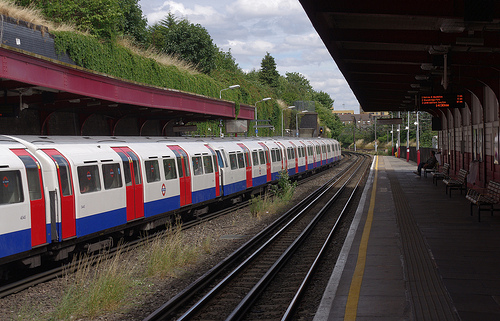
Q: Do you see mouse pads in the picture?
A: No, there are no mouse pads.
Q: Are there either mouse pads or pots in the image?
A: No, there are no mouse pads or pots.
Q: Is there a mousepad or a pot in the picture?
A: No, there are no mouse pads or pots.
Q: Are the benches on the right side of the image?
A: Yes, the benches are on the right of the image.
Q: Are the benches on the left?
A: No, the benches are on the right of the image.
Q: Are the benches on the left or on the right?
A: The benches are on the right of the image.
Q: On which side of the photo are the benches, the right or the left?
A: The benches are on the right of the image.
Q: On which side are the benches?
A: The benches are on the right of the image.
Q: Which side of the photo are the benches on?
A: The benches are on the right of the image.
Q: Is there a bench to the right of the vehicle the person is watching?
A: Yes, there are benches to the right of the train.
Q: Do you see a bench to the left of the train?
A: No, the benches are to the right of the train.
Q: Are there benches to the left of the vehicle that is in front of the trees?
A: No, the benches are to the right of the train.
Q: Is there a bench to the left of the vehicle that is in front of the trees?
A: No, the benches are to the right of the train.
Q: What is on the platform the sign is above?
A: The benches are on the platform.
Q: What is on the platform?
A: The benches are on the platform.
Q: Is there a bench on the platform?
A: Yes, there are benches on the platform.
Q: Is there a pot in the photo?
A: No, there are no pots.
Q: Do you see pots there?
A: No, there are no pots.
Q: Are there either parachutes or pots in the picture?
A: No, there are no pots or parachutes.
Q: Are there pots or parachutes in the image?
A: No, there are no pots or parachutes.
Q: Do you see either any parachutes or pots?
A: No, there are no pots or parachutes.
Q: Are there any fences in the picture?
A: No, there are no fences.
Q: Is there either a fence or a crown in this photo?
A: No, there are no fences or crowns.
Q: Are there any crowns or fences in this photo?
A: No, there are no fences or crowns.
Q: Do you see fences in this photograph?
A: No, there are no fences.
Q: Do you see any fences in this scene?
A: No, there are no fences.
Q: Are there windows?
A: Yes, there are windows.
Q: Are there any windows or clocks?
A: Yes, there are windows.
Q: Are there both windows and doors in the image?
A: Yes, there are both windows and doors.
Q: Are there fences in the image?
A: No, there are no fences.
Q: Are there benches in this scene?
A: Yes, there is a bench.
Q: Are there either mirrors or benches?
A: Yes, there is a bench.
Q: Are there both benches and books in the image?
A: No, there is a bench but no books.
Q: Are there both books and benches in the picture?
A: No, there is a bench but no books.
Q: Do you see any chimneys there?
A: No, there are no chimneys.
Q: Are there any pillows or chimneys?
A: No, there are no chimneys or pillows.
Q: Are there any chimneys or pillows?
A: No, there are no chimneys or pillows.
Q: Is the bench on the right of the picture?
A: Yes, the bench is on the right of the image.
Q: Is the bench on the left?
A: No, the bench is on the right of the image.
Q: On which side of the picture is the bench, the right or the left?
A: The bench is on the right of the image.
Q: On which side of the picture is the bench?
A: The bench is on the right of the image.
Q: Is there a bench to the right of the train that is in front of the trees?
A: Yes, there is a bench to the right of the train.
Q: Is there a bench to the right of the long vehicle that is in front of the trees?
A: Yes, there is a bench to the right of the train.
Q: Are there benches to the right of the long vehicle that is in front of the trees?
A: Yes, there is a bench to the right of the train.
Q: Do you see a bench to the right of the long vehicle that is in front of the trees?
A: Yes, there is a bench to the right of the train.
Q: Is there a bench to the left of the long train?
A: No, the bench is to the right of the train.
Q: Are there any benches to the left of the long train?
A: No, the bench is to the right of the train.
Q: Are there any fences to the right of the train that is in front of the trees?
A: No, there is a bench to the right of the train.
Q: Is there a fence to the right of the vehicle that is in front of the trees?
A: No, there is a bench to the right of the train.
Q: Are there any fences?
A: No, there are no fences.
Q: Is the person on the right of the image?
A: Yes, the person is on the right of the image.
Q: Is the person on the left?
A: No, the person is on the right of the image.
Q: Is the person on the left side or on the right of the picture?
A: The person is on the right of the image.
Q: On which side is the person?
A: The person is on the right of the image.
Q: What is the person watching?
A: The person is watching the train.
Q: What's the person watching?
A: The person is watching the train.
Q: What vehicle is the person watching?
A: The person is watching the train.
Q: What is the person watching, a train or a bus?
A: The person is watching a train.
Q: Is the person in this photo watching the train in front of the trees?
A: Yes, the person is watching the train.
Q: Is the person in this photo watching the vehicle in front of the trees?
A: Yes, the person is watching the train.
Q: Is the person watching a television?
A: No, the person is watching the train.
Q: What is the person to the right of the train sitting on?
A: The person is sitting on the bench.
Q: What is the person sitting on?
A: The person is sitting on the bench.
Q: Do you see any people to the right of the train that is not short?
A: Yes, there is a person to the right of the train.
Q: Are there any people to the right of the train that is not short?
A: Yes, there is a person to the right of the train.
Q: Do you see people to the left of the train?
A: No, the person is to the right of the train.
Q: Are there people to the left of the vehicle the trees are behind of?
A: No, the person is to the right of the train.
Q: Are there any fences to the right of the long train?
A: No, there is a person to the right of the train.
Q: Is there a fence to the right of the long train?
A: No, there is a person to the right of the train.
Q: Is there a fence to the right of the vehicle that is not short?
A: No, there is a person to the right of the train.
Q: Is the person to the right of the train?
A: Yes, the person is to the right of the train.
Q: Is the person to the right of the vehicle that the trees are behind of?
A: Yes, the person is to the right of the train.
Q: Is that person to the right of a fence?
A: No, the person is to the right of the train.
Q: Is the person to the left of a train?
A: No, the person is to the right of a train.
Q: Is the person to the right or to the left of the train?
A: The person is to the right of the train.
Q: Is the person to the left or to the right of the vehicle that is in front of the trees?
A: The person is to the right of the train.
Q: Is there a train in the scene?
A: Yes, there is a train.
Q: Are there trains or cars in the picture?
A: Yes, there is a train.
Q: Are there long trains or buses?
A: Yes, there is a long train.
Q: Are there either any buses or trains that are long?
A: Yes, the train is long.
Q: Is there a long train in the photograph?
A: Yes, there is a long train.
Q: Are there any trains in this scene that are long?
A: Yes, there is a train that is long.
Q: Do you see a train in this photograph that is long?
A: Yes, there is a train that is long.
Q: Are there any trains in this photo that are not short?
A: Yes, there is a long train.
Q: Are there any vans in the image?
A: No, there are no vans.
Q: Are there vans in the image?
A: No, there are no vans.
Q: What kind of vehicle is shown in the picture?
A: The vehicle is a train.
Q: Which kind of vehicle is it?
A: The vehicle is a train.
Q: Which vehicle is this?
A: This is a train.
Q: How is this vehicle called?
A: This is a train.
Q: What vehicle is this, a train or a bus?
A: This is a train.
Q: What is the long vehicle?
A: The vehicle is a train.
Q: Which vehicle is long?
A: The vehicle is a train.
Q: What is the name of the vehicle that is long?
A: The vehicle is a train.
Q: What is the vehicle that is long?
A: The vehicle is a train.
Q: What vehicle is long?
A: The vehicle is a train.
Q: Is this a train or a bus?
A: This is a train.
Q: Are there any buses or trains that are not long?
A: No, there is a train but it is long.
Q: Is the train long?
A: Yes, the train is long.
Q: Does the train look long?
A: Yes, the train is long.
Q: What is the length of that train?
A: The train is long.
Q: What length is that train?
A: The train is long.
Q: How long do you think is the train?
A: The train is long.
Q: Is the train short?
A: No, the train is long.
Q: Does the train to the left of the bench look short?
A: No, the train is long.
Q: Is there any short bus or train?
A: No, there is a train but it is long.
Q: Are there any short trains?
A: No, there is a train but it is long.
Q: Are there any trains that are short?
A: No, there is a train but it is long.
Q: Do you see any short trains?
A: No, there is a train but it is long.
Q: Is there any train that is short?
A: No, there is a train but it is long.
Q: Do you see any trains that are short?
A: No, there is a train but it is long.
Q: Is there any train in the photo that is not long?
A: No, there is a train but it is long.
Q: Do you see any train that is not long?
A: No, there is a train but it is long.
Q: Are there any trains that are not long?
A: No, there is a train but it is long.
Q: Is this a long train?
A: Yes, this is a long train.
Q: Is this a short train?
A: No, this is a long train.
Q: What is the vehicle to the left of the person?
A: The vehicle is a train.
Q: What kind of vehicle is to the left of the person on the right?
A: The vehicle is a train.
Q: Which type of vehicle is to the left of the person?
A: The vehicle is a train.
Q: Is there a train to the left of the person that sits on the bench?
A: Yes, there is a train to the left of the person.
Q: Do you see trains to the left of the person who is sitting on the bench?
A: Yes, there is a train to the left of the person.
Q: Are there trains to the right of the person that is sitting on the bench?
A: No, the train is to the left of the person.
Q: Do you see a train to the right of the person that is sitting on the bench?
A: No, the train is to the left of the person.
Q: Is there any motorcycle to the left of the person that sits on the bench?
A: No, there is a train to the left of the person.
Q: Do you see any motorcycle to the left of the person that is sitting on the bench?
A: No, there is a train to the left of the person.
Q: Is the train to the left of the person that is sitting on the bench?
A: Yes, the train is to the left of the person.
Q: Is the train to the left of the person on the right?
A: Yes, the train is to the left of the person.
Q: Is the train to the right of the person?
A: No, the train is to the left of the person.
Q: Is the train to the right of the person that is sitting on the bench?
A: No, the train is to the left of the person.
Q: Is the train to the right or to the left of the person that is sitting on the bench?
A: The train is to the left of the person.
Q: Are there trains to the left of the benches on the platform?
A: Yes, there is a train to the left of the benches.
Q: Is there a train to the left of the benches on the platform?
A: Yes, there is a train to the left of the benches.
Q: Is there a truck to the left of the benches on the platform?
A: No, there is a train to the left of the benches.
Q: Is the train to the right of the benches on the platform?
A: No, the train is to the left of the benches.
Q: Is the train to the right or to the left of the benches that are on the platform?
A: The train is to the left of the benches.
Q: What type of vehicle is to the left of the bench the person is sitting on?
A: The vehicle is a train.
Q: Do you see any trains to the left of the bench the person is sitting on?
A: Yes, there is a train to the left of the bench.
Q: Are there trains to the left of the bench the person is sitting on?
A: Yes, there is a train to the left of the bench.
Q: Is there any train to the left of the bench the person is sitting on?
A: Yes, there is a train to the left of the bench.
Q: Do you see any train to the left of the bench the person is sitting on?
A: Yes, there is a train to the left of the bench.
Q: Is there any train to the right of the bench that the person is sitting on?
A: No, the train is to the left of the bench.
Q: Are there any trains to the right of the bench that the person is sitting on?
A: No, the train is to the left of the bench.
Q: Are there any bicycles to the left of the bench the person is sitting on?
A: No, there is a train to the left of the bench.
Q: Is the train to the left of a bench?
A: Yes, the train is to the left of a bench.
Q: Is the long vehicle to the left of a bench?
A: Yes, the train is to the left of a bench.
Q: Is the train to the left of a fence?
A: No, the train is to the left of a bench.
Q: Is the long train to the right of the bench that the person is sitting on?
A: No, the train is to the left of the bench.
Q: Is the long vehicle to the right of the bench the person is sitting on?
A: No, the train is to the left of the bench.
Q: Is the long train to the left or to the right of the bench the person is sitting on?
A: The train is to the left of the bench.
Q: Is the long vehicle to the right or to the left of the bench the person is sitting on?
A: The train is to the left of the bench.